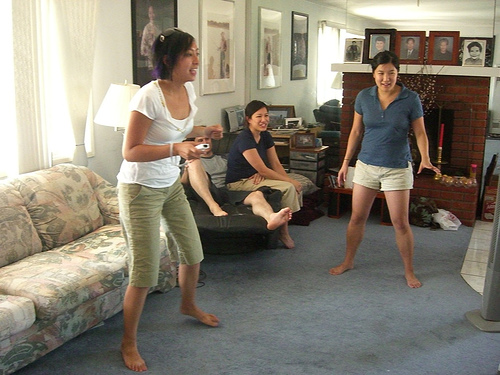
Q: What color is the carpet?
A: Blue.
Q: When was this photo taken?
A: During the day.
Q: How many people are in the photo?
A: 4.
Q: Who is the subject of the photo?
A: The people.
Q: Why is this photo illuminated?
A: Windows.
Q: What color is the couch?
A: Cream.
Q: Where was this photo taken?
A: In the living room.